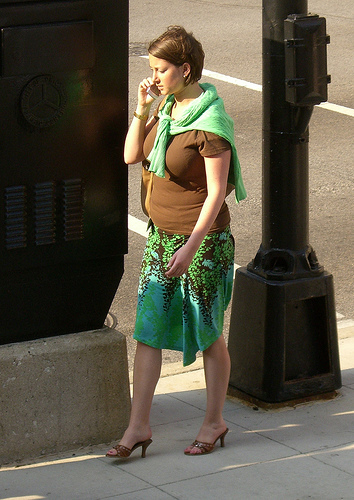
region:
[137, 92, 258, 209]
The green sweater around the lady's shoulders.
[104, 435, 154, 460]
The brown shoe on the lady's left foot.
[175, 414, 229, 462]
The brown shoe on the lady's right foot.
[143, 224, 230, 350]
The green and brown skirt the lady is wearing.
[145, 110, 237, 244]
The brown shirt the lady is wearing.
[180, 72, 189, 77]
The earring in the lady's ear.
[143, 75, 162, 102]
The cell phone the lady is talking on.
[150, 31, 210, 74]
The lady's short hair.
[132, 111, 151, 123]
The watch on the lady's left wrist.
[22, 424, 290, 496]
The sidewalk the lady is walking on.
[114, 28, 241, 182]
The woman is holding a phone.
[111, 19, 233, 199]
The woman is talking on a cell phone.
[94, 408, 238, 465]
The shoes slip on.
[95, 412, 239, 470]
The shoes are brown.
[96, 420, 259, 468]
The shoes have a heel.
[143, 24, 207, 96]
The woman's hair is short.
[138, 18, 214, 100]
The woman's hair is tousled.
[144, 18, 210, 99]
The woman's hair is brown.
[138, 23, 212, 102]
The woman has hair.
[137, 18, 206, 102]
The woman is wearing an earring.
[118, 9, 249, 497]
lady walking on sidewalk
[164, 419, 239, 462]
brown toeless shoe on foot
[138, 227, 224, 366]
green and brown print skirt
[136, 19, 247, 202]
woman with green sweater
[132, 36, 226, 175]
woman holding cell phone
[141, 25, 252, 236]
woman in brown shirt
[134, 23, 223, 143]
lady with short brown hair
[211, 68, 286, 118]
white line painted on roadway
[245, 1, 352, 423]
black traffic signal on sidewalk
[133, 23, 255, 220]
sweater tied around shoulders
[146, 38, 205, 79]
a woman's short brown hair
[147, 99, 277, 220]
a green shirt tied around a woman's neck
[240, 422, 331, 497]
white concrete tiled sidewalk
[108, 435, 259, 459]
brown high heels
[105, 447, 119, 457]
red nail polish on a woman's toes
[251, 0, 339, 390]
a large black metal post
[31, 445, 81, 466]
sunlight reflecting on the concrete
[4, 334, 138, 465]
a concrete corner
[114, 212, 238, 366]
a green brown and blue skirt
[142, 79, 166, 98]
a cell phone in a woman's hand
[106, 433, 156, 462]
the shoes are brwon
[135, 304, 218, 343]
the dress is green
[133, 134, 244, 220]
the shirt is brown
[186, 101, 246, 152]
the sweater is green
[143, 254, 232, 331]
the dress is colored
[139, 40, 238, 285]
she is talking on the phone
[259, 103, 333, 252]
the pole is black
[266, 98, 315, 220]
the pole is metallic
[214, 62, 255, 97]
white stripe is in the parking lot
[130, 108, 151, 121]
she has a watch on the wrist